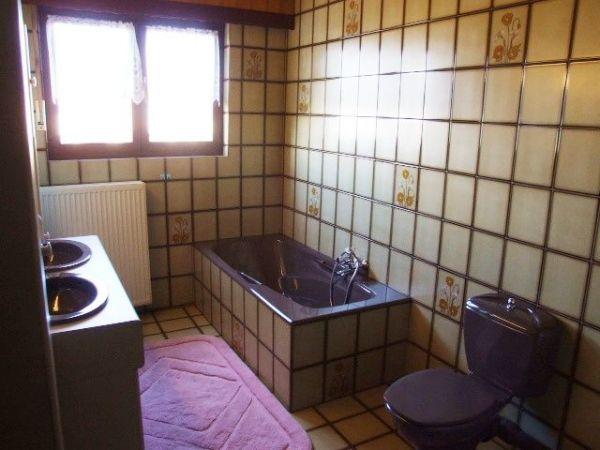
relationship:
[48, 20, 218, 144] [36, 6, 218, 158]
sunlight coming from window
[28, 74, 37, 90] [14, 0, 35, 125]
knob on cabinet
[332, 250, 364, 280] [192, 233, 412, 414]
faucet in bathtub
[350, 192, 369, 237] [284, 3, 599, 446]
tile in wall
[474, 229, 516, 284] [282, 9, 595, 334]
tile in wall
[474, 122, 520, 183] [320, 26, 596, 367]
tile in a wall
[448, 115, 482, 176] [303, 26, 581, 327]
tile on wall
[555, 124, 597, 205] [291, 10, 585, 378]
tile on wall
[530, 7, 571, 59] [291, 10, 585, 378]
tile on wall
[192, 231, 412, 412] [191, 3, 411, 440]
bathtub at corner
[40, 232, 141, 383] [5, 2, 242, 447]
sink on left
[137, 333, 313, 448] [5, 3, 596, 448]
carpet in bathroom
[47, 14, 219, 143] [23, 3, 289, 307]
window in background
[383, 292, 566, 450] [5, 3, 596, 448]
system in bathroom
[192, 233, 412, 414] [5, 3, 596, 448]
bathtub in bathroom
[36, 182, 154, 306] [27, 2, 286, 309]
radiator on wall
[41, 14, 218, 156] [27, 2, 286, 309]
window are on wall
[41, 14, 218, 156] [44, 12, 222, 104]
window have curtains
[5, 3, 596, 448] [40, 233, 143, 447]
bathroom has counter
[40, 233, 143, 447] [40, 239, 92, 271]
counter has sink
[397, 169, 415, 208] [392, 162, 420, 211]
pattern on tile